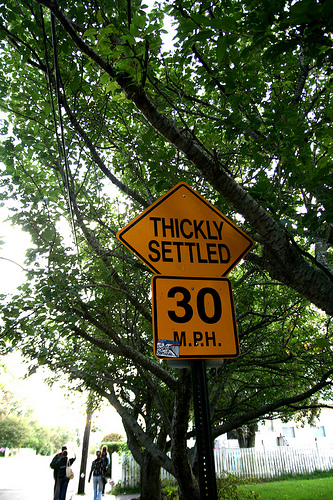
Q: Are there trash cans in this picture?
A: No, there are no trash cans.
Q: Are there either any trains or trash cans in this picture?
A: No, there are no trash cans or trains.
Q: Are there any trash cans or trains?
A: No, there are no trash cans or trains.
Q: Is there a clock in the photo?
A: No, there are no clocks.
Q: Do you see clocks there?
A: No, there are no clocks.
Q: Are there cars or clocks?
A: No, there are no clocks or cars.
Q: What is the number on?
A: The number is on the sign.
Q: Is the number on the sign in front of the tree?
A: Yes, the number is on the sign.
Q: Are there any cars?
A: No, there are no cars.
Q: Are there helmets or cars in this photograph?
A: No, there are no cars or helmets.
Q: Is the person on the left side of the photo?
A: Yes, the person is on the left of the image.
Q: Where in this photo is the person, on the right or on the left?
A: The person is on the left of the image.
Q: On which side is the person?
A: The person is on the left of the image.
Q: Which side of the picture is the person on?
A: The person is on the left of the image.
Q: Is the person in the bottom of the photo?
A: Yes, the person is in the bottom of the image.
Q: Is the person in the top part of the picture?
A: No, the person is in the bottom of the image.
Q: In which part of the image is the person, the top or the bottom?
A: The person is in the bottom of the image.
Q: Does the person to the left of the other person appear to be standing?
A: Yes, the person is standing.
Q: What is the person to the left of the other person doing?
A: The person is standing.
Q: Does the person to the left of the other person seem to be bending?
A: No, the person is standing.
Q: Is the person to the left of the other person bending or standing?
A: The person is standing.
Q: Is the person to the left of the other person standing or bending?
A: The person is standing.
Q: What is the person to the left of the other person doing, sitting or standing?
A: The person is standing.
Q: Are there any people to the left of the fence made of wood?
A: Yes, there is a person to the left of the fence.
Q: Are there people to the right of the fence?
A: No, the person is to the left of the fence.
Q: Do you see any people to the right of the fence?
A: No, the person is to the left of the fence.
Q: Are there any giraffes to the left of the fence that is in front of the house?
A: No, there is a person to the left of the fence.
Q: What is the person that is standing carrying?
A: The person is carrying a bag.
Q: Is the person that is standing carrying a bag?
A: Yes, the person is carrying a bag.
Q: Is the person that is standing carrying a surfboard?
A: No, the person is carrying a bag.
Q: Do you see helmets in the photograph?
A: No, there are no helmets.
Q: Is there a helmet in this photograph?
A: No, there are no helmets.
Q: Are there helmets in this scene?
A: No, there are no helmets.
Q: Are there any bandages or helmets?
A: No, there are no helmets or bandages.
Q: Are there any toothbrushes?
A: No, there are no toothbrushes.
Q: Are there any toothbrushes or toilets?
A: No, there are no toothbrushes or toilets.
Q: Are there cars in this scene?
A: No, there are no cars.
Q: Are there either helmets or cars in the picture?
A: No, there are no cars or helmets.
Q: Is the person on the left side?
A: Yes, the person is on the left of the image.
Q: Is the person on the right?
A: No, the person is on the left of the image.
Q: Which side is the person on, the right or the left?
A: The person is on the left of the image.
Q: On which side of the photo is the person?
A: The person is on the left of the image.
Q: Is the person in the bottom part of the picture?
A: Yes, the person is in the bottom of the image.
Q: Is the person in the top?
A: No, the person is in the bottom of the image.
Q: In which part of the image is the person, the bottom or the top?
A: The person is in the bottom of the image.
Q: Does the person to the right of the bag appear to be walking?
A: Yes, the person is walking.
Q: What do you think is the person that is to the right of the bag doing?
A: The person is walking.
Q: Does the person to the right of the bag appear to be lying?
A: No, the person is walking.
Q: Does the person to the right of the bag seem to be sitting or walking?
A: The person is walking.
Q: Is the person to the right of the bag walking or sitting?
A: The person is walking.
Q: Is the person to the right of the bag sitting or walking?
A: The person is walking.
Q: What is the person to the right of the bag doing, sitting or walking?
A: The person is walking.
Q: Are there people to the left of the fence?
A: Yes, there is a person to the left of the fence.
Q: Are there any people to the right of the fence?
A: No, the person is to the left of the fence.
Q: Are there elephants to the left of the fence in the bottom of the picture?
A: No, there is a person to the left of the fence.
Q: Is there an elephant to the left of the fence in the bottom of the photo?
A: No, there is a person to the left of the fence.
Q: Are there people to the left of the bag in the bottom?
A: No, the person is to the right of the bag.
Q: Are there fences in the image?
A: Yes, there is a fence.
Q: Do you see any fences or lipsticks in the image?
A: Yes, there is a fence.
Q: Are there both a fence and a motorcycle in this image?
A: No, there is a fence but no motorcycles.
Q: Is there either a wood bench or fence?
A: Yes, there is a wood fence.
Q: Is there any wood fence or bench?
A: Yes, there is a wood fence.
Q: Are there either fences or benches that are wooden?
A: Yes, the fence is wooden.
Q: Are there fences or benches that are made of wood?
A: Yes, the fence is made of wood.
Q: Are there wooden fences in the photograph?
A: Yes, there is a wood fence.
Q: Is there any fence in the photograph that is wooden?
A: Yes, there is a fence that is wooden.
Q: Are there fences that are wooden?
A: Yes, there is a fence that is wooden.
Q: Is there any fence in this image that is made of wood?
A: Yes, there is a fence that is made of wood.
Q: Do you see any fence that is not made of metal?
A: Yes, there is a fence that is made of wood.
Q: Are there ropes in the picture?
A: No, there are no ropes.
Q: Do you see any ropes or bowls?
A: No, there are no ropes or bowls.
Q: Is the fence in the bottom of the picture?
A: Yes, the fence is in the bottom of the image.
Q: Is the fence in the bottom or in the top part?
A: The fence is in the bottom of the image.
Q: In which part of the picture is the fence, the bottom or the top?
A: The fence is in the bottom of the image.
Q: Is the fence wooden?
A: Yes, the fence is wooden.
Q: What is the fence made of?
A: The fence is made of wood.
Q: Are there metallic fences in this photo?
A: No, there is a fence but it is wooden.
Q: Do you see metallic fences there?
A: No, there is a fence but it is wooden.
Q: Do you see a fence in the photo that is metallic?
A: No, there is a fence but it is wooden.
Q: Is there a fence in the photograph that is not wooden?
A: No, there is a fence but it is wooden.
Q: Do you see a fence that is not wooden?
A: No, there is a fence but it is wooden.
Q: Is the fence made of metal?
A: No, the fence is made of wood.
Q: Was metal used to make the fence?
A: No, the fence is made of wood.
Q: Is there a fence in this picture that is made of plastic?
A: No, there is a fence but it is made of wood.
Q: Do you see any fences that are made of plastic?
A: No, there is a fence but it is made of wood.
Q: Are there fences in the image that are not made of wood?
A: No, there is a fence but it is made of wood.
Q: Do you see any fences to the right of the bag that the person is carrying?
A: Yes, there is a fence to the right of the bag.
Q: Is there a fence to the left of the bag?
A: No, the fence is to the right of the bag.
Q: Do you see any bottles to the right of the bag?
A: No, there is a fence to the right of the bag.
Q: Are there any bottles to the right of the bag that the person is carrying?
A: No, there is a fence to the right of the bag.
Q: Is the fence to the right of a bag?
A: Yes, the fence is to the right of a bag.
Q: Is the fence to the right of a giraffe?
A: No, the fence is to the right of a bag.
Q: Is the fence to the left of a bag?
A: No, the fence is to the right of a bag.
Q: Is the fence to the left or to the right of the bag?
A: The fence is to the right of the bag.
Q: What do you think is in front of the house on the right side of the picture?
A: The fence is in front of the house.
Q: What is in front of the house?
A: The fence is in front of the house.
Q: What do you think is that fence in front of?
A: The fence is in front of the house.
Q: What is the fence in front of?
A: The fence is in front of the house.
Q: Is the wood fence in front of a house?
A: Yes, the fence is in front of a house.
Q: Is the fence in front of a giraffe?
A: No, the fence is in front of a house.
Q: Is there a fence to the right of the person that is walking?
A: Yes, there is a fence to the right of the person.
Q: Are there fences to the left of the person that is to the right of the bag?
A: No, the fence is to the right of the person.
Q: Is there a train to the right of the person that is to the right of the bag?
A: No, there is a fence to the right of the person.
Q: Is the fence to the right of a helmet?
A: No, the fence is to the right of the person.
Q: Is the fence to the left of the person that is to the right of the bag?
A: No, the fence is to the right of the person.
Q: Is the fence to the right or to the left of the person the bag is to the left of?
A: The fence is to the right of the person.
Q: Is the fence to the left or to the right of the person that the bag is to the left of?
A: The fence is to the right of the person.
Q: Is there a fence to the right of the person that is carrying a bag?
A: Yes, there is a fence to the right of the person.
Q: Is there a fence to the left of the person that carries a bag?
A: No, the fence is to the right of the person.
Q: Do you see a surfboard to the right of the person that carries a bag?
A: No, there is a fence to the right of the person.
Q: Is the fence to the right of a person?
A: Yes, the fence is to the right of a person.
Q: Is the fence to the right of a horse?
A: No, the fence is to the right of a person.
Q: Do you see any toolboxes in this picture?
A: No, there are no toolboxes.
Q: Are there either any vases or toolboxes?
A: No, there are no toolboxes or vases.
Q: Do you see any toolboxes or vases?
A: No, there are no toolboxes or vases.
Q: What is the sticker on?
A: The sticker is on the sign.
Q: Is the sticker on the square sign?
A: Yes, the sticker is on the sign.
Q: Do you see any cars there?
A: No, there are no cars.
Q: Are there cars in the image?
A: No, there are no cars.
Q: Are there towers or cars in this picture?
A: No, there are no cars or towers.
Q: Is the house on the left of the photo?
A: No, the house is on the right of the image.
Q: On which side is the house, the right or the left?
A: The house is on the right of the image.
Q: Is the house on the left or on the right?
A: The house is on the right of the image.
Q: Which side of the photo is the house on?
A: The house is on the right of the image.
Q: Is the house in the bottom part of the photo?
A: Yes, the house is in the bottom of the image.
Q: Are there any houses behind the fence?
A: Yes, there is a house behind the fence.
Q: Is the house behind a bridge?
A: No, the house is behind the fence.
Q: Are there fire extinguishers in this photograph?
A: No, there are no fire extinguishers.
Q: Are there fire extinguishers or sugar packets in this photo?
A: No, there are no fire extinguishers or sugar packets.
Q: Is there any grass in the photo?
A: Yes, there is grass.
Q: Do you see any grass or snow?
A: Yes, there is grass.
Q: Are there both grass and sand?
A: No, there is grass but no sand.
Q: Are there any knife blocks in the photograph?
A: No, there are no knife blocks.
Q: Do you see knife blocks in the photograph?
A: No, there are no knife blocks.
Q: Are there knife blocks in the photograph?
A: No, there are no knife blocks.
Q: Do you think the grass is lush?
A: Yes, the grass is lush.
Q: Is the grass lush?
A: Yes, the grass is lush.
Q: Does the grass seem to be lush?
A: Yes, the grass is lush.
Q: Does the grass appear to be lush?
A: Yes, the grass is lush.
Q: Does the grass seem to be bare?
A: No, the grass is lush.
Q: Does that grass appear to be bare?
A: No, the grass is lush.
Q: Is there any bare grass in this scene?
A: No, there is grass but it is lush.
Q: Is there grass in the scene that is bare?
A: No, there is grass but it is lush.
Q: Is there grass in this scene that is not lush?
A: No, there is grass but it is lush.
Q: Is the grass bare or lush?
A: The grass is lush.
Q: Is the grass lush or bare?
A: The grass is lush.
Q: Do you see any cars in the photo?
A: No, there are no cars.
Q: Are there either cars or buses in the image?
A: No, there are no cars or buses.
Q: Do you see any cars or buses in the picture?
A: No, there are no cars or buses.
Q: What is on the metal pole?
A: The sign is on the pole.